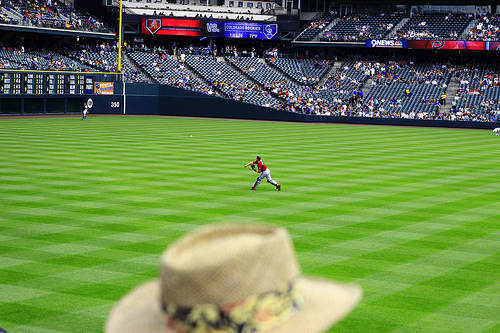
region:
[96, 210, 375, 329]
Hat with floral accented band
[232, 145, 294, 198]
In-field baseball player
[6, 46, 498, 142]
Sparsely populated arena seating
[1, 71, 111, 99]
Digital baseball score board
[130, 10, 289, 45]
Digital screen for team information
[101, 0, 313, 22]
Sport anchor reporting box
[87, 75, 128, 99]
Baseball sponsor sign for audience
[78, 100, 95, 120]
Outfielder base ball player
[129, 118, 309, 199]
Baseball player practicing their throw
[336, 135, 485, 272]
Baseball outfield green checkerboard lawn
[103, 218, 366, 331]
A brown sun hat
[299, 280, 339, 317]
The brim of the hat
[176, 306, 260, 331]
A decorative band on the hat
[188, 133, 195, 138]
The pitched ball in the air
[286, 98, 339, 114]
Spectators in the stands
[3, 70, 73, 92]
The score board on the far side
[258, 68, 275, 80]
Blue seats in the stands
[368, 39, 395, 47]
A blue advertisement board with white writings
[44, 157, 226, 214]
The greenish playing field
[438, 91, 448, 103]
A person in a yellow shirt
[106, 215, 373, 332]
straw hat with band on it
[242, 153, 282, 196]
outfielder running in field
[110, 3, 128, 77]
yellow foul pole in background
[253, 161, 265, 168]
red jersey of fielder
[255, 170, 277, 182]
gray pants of fielder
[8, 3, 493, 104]
crowd of spectators watching the game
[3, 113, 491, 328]
green grass of the outfield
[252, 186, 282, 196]
cleats of baseball player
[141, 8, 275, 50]
large scoreboard in background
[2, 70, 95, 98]
scoreboard on outfield wall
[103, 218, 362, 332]
Blurry straw hat in foreground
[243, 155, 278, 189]
Baseball player in throwing position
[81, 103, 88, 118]
baseball player in outfield, far in the distance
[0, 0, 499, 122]
Many spectators watching baseball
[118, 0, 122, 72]
Foul ball pole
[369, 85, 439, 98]
rows of empty seats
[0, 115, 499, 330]
a stretch of grass on a baseball field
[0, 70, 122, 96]
a board with statistics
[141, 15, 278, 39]
an electronic scoreboard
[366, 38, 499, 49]
an electronic billboard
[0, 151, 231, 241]
a patch of checkered grass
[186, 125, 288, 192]
a man throwing a baseball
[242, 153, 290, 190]
a man in a rad uniform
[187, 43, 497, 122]
people in a stadium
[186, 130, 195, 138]
a baseball flying through the air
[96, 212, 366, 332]
a womans straw hat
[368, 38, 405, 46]
a news billboard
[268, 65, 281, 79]
a group of empty seats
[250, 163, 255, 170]
a baseballer's glove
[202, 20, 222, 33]
the word vs on a sign